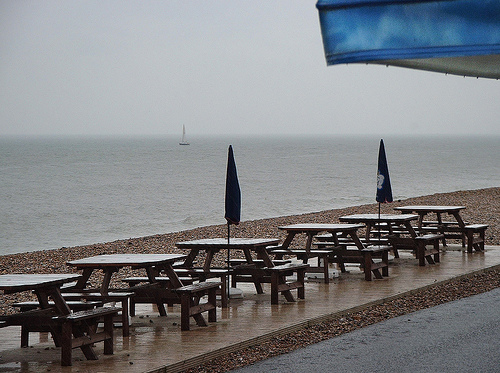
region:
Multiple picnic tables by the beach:
[3, 135, 490, 368]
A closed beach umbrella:
[223, 138, 239, 304]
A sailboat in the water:
[178, 125, 188, 144]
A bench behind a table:
[180, 278, 222, 328]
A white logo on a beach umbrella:
[376, 170, 388, 191]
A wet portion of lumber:
[231, 293, 312, 325]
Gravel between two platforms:
[306, 275, 499, 322]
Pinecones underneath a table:
[138, 310, 180, 333]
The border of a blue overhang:
[316, 0, 499, 64]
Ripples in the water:
[32, 170, 174, 226]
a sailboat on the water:
[176, 122, 193, 148]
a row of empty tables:
[0, 206, 488, 365]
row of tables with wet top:
[3, 207, 488, 365]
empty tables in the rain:
[0, 203, 490, 365]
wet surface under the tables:
[0, 241, 498, 372]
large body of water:
[1, 136, 498, 257]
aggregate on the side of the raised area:
[172, 263, 498, 372]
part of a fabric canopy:
[315, 1, 498, 83]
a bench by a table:
[53, 306, 119, 363]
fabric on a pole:
[222, 146, 240, 303]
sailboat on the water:
[176, 118, 202, 150]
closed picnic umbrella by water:
[215, 140, 247, 239]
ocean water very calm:
[40, 145, 156, 202]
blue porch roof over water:
[317, 6, 494, 61]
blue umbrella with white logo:
[372, 134, 407, 219]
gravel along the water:
[37, 228, 197, 246]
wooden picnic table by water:
[276, 213, 381, 276]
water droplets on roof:
[327, 58, 497, 80]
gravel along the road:
[274, 335, 314, 349]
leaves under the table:
[137, 310, 159, 328]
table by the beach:
[0, 266, 123, 356]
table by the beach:
[67, 250, 224, 323]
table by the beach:
[177, 236, 307, 301]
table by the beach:
[280, 220, 386, 278]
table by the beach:
[339, 211, 440, 261]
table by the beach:
[394, 201, 489, 251]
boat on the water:
[177, 120, 200, 153]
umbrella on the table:
[216, 135, 243, 296]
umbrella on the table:
[370, 132, 396, 257]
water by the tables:
[67, 165, 114, 192]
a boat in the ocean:
[174, 123, 195, 148]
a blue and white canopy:
[311, 2, 498, 84]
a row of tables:
[11, 201, 489, 332]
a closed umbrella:
[218, 141, 243, 294]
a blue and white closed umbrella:
[372, 134, 392, 250]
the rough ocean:
[38, 150, 206, 231]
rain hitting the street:
[353, 318, 454, 352]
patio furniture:
[181, 139, 300, 302]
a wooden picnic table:
[65, 243, 219, 330]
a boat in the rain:
[163, 114, 205, 156]